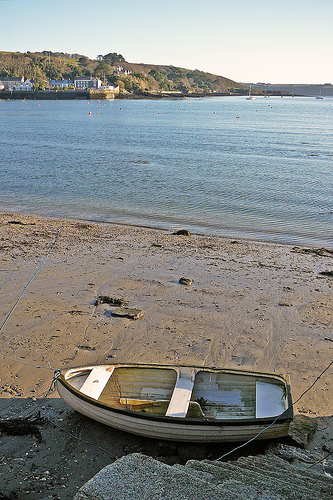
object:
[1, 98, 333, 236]
body of water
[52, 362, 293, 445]
boat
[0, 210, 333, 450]
shore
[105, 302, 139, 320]
rock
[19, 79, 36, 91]
building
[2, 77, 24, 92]
building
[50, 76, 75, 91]
building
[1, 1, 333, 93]
sky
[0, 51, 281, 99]
mountain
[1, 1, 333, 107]
background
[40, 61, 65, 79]
trees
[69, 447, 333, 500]
steps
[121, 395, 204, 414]
oars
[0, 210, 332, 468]
sand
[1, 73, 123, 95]
buildings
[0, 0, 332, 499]
bouys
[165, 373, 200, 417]
seat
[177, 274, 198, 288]
rock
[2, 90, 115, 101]
wall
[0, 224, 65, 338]
rope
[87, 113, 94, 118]
buoy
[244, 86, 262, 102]
sailboat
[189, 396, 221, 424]
rudder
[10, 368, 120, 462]
rope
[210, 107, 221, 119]
buoy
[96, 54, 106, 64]
building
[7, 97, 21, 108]
buoys